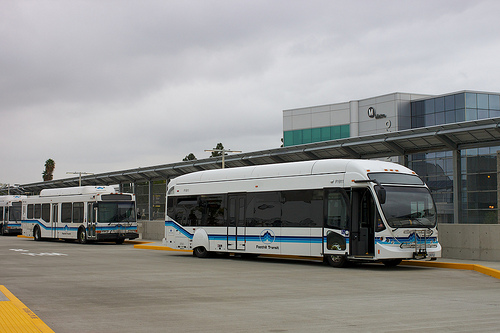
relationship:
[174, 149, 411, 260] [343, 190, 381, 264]
bus has door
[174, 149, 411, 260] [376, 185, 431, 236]
bus has windshield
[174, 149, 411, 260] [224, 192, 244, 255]
bus has exit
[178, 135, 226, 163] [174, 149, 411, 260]
trees above bus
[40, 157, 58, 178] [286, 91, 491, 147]
tree behind building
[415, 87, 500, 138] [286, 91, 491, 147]
windows on building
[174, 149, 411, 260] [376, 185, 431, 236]
bus has window